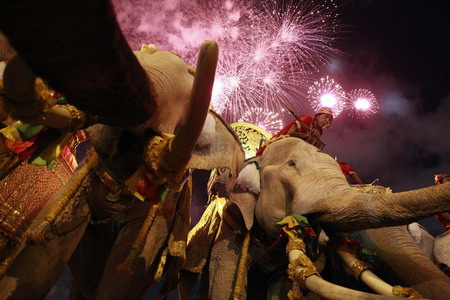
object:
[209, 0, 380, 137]
fireworks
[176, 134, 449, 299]
elephant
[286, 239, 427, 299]
tusks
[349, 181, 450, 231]
trunk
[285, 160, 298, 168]
eye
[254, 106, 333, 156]
person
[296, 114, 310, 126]
red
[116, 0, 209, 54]
smoke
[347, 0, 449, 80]
sky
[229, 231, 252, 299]
rope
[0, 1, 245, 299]
elephant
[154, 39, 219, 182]
tusk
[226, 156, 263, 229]
ear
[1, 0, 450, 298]
festivities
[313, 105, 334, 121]
hat